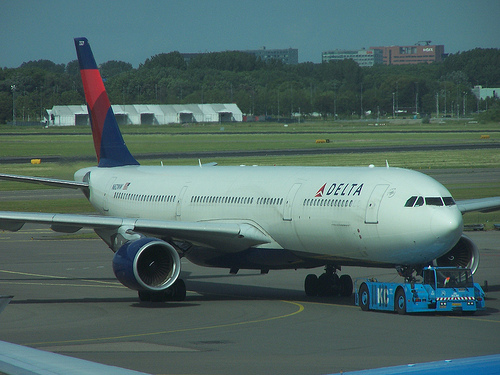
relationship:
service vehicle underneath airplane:
[354, 265, 485, 315] [1, 35, 500, 304]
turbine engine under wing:
[113, 237, 181, 290] [0, 210, 270, 249]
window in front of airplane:
[426, 197, 443, 207] [1, 35, 500, 304]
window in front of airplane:
[441, 196, 456, 206] [1, 35, 500, 304]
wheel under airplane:
[304, 272, 320, 296] [1, 35, 500, 304]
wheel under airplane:
[341, 273, 353, 298] [1, 35, 500, 304]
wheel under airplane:
[175, 279, 187, 300] [1, 35, 500, 304]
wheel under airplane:
[321, 273, 333, 298] [1, 35, 500, 304]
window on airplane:
[349, 200, 353, 207] [1, 35, 500, 304]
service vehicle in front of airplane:
[354, 265, 485, 315] [1, 35, 500, 304]